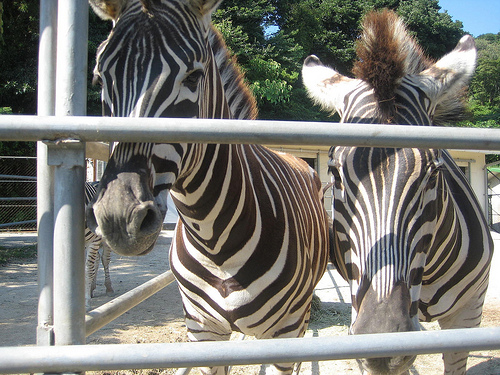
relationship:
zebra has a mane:
[301, 8, 499, 374] [352, 8, 462, 121]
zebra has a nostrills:
[91, 1, 327, 373] [84, 204, 161, 235]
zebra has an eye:
[91, 1, 327, 373] [94, 72, 106, 87]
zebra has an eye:
[301, 8, 499, 374] [428, 163, 442, 181]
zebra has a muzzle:
[301, 8, 499, 374] [352, 225, 423, 374]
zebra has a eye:
[301, 8, 499, 374] [329, 162, 345, 187]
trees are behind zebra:
[1, 0, 500, 130] [301, 8, 499, 374]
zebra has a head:
[301, 8, 499, 374] [305, 9, 477, 375]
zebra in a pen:
[301, 8, 499, 374] [0, 1, 500, 374]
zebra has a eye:
[301, 8, 499, 374] [428, 163, 442, 181]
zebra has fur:
[301, 8, 499, 374] [306, 5, 495, 375]